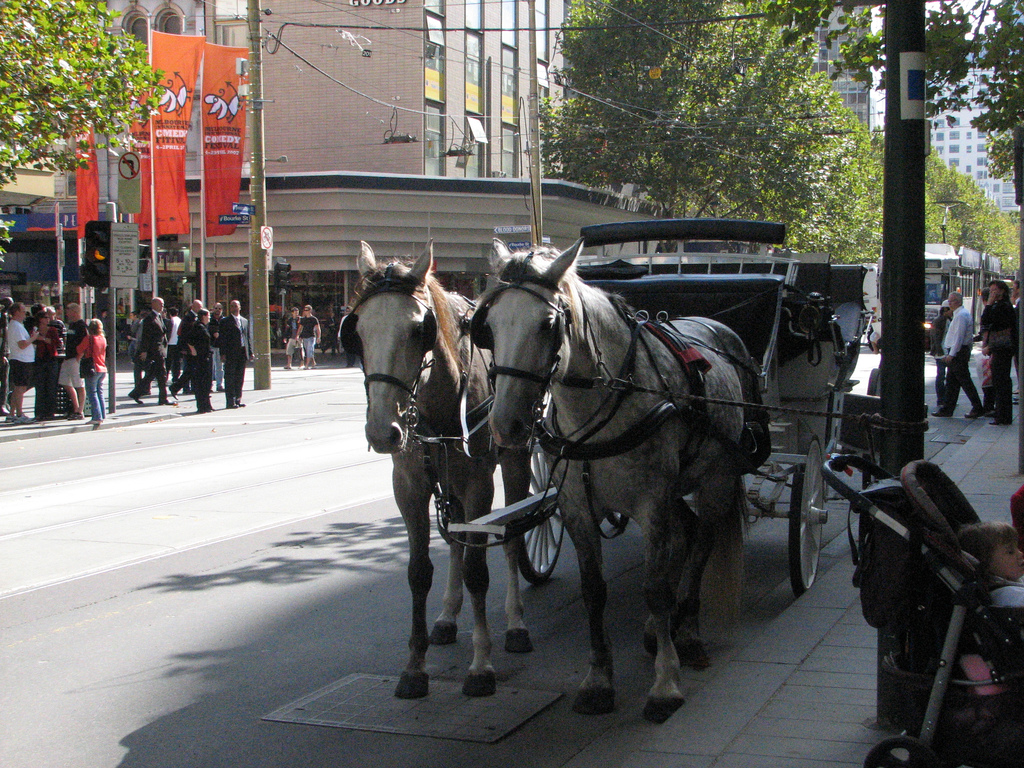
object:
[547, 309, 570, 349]
blinders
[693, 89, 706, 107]
leaves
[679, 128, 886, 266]
tree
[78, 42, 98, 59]
leaves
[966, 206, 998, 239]
leaves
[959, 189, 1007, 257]
tree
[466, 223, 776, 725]
horse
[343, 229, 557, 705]
horse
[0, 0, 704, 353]
wall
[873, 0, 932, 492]
pole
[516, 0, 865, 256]
tree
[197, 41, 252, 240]
banners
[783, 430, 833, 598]
wheel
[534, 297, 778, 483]
cloth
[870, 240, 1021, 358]
bus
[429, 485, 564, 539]
bar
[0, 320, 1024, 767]
road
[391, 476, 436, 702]
leg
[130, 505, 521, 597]
shadow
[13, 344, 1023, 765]
view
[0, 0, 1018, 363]
view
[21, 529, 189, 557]
lines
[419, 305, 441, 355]
blinders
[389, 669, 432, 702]
foot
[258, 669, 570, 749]
panel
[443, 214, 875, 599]
carriage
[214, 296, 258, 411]
people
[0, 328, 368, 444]
sidewalk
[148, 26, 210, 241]
banners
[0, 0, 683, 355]
building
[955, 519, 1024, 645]
child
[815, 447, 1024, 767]
stroller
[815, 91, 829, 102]
leaf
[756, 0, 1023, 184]
tree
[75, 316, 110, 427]
woman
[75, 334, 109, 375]
jacket